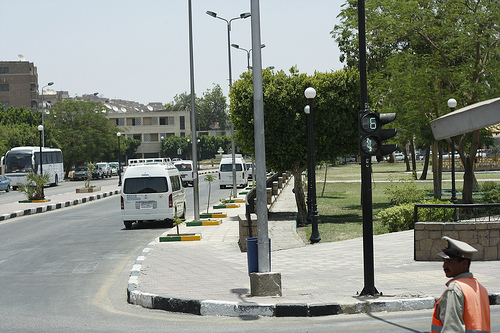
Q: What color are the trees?
A: Green.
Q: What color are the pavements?
A: Black and white.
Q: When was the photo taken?
A: Daytime.